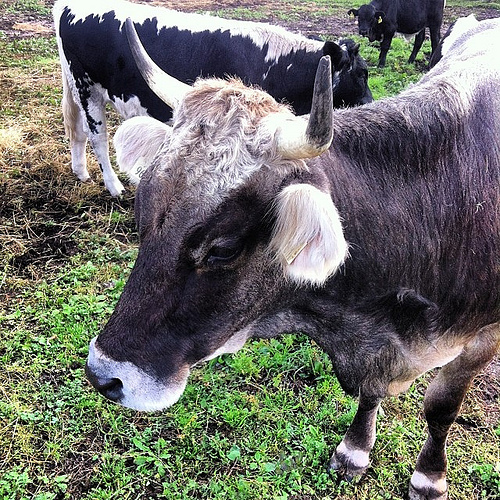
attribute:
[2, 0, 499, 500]
grass — yellow , dead , green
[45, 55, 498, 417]
cow — gray, white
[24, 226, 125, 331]
grass — green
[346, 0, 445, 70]
cow — black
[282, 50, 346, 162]
horn — large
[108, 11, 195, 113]
horn — large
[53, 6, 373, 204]
cow — black, white, spotted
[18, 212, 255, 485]
field — grass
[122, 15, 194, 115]
horn — large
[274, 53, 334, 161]
horn — large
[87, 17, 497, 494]
cow — gray